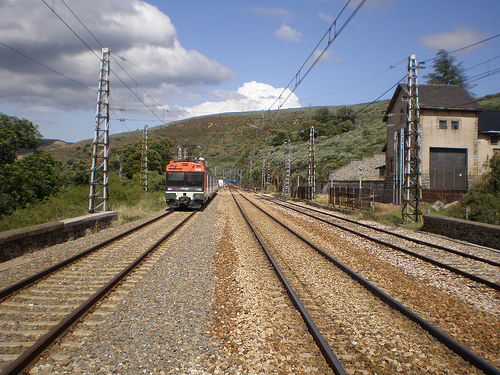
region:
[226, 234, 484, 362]
metal train tracks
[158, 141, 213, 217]
orange train engine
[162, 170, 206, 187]
windshield of orange train engine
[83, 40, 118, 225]
metal tower next to train tracks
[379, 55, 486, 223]
old building next to train tracks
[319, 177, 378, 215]
fence along side train tracks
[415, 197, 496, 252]
stone wall along side train tracks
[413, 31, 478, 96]
top of pine tree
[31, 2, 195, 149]
electrical wire over train tracks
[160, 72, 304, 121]
white puffy cloud on the horizon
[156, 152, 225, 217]
a train going forward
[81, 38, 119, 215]
metal tower to hold electrical lines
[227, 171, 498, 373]
railroad tracks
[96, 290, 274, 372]
stone gravel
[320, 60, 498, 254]
old building next to railroad tracks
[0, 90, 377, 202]
grassy hills in the distance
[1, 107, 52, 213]
green tree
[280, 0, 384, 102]
electrical wire above the ground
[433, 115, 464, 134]
small windows on a building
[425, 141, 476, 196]
large door on a building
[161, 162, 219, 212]
the train is red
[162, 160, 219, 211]
the train is on the tracks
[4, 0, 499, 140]
the sky is cloudy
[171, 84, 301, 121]
the cloud is fluffy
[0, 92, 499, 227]
the hills are green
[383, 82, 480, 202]
the building is beige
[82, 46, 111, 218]
the pole is silver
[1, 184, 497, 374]
the ground is brown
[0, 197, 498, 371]
the tracks are dark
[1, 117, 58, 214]
the trees are green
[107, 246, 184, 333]
Gravel beside train track.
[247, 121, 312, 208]
Electric lines bty tracks.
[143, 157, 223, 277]
Orange and white train.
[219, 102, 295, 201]
A large grassy hill.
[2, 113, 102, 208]
Green trees and grass.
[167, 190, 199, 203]
Lower front of a train.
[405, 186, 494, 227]
Rocks beside a small rock wall.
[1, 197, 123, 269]
Curb beside rail road tracks.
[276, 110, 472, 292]
Building beside rail road track.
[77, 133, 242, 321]
A train on the tracks.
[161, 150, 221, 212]
red train on train track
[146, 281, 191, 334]
gravel and rock next to train track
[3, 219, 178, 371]
brown metal train track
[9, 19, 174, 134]
black power line and electric tower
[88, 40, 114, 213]
metal electric tower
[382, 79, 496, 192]
house with brown roof and side door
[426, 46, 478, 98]
top of tall green evergreen tree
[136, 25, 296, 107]
white and grey clouds in blue sky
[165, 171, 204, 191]
two front windows of train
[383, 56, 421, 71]
tall grey street light